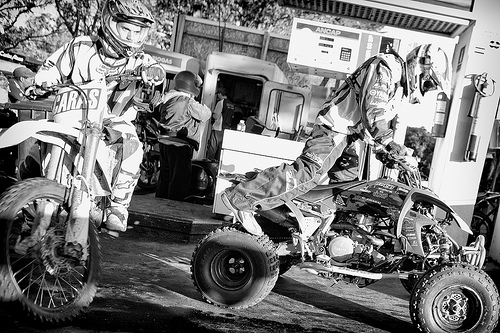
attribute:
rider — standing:
[235, 38, 446, 218]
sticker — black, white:
[49, 92, 102, 112]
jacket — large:
[53, 41, 150, 110]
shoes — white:
[103, 201, 130, 233]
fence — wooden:
[9, 101, 60, 120]